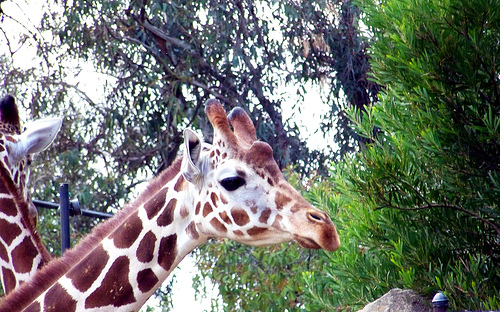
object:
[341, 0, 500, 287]
trees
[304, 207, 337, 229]
nose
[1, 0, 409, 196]
sky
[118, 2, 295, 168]
trees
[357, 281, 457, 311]
rock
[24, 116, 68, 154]
ear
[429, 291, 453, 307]
hat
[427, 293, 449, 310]
head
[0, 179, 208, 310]
neck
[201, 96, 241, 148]
horn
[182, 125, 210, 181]
ear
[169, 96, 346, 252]
head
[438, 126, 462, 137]
leaves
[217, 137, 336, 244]
face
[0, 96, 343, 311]
giraffe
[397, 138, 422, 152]
leaves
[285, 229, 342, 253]
mouth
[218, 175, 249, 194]
eye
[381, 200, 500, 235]
sticks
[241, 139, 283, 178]
forehead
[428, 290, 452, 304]
top